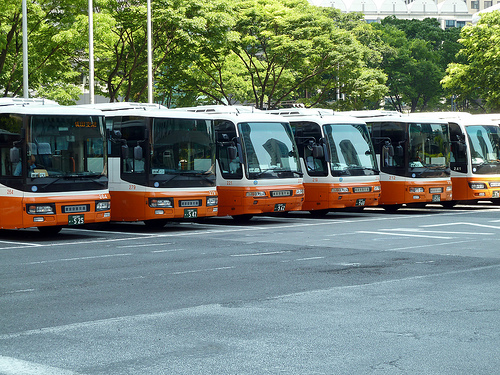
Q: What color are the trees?
A: Green.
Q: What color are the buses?
A: White and orange.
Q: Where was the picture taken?
A: In a parking lot.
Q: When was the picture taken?
A: In the daytime.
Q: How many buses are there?
A: Six.